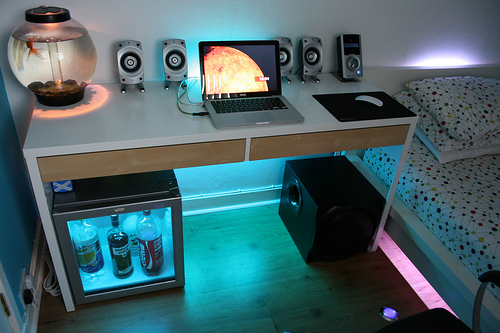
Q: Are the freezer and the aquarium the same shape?
A: No, the aquarium is round and the freezer is square.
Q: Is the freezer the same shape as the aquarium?
A: No, the aquarium is round and the freezer is square.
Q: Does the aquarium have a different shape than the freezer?
A: Yes, the aquarium is round and the freezer is square.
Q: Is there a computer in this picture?
A: Yes, there is a computer.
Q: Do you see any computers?
A: Yes, there is a computer.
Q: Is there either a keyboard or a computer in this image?
A: Yes, there is a computer.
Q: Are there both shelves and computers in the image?
A: No, there is a computer but no shelves.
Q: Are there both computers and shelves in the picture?
A: No, there is a computer but no shelves.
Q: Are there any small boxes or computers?
A: Yes, there is a small computer.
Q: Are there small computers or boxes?
A: Yes, there is a small computer.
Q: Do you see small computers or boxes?
A: Yes, there is a small computer.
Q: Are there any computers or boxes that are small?
A: Yes, the computer is small.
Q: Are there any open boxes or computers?
A: Yes, there is an open computer.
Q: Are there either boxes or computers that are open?
A: Yes, the computer is open.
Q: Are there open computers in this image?
A: Yes, there is an open computer.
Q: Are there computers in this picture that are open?
A: Yes, there is an open computer.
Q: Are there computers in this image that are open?
A: Yes, there is a computer that is open.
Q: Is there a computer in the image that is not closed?
A: Yes, there is a open computer.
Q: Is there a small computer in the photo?
A: Yes, there is a small computer.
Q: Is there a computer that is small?
A: Yes, there is a computer that is small.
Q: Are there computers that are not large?
A: Yes, there is a small computer.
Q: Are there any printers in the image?
A: No, there are no printers.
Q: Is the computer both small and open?
A: Yes, the computer is small and open.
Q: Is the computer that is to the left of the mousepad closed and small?
A: No, the computer is small but open.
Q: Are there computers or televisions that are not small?
A: No, there is a computer but it is small.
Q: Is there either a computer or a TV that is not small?
A: No, there is a computer but it is small.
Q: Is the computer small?
A: Yes, the computer is small.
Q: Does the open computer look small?
A: Yes, the computer is small.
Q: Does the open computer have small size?
A: Yes, the computer is small.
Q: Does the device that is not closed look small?
A: Yes, the computer is small.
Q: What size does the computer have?
A: The computer has small size.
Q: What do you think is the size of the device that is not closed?
A: The computer is small.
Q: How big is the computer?
A: The computer is small.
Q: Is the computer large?
A: No, the computer is small.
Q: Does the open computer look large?
A: No, the computer is small.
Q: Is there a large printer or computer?
A: No, there is a computer but it is small.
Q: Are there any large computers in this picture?
A: No, there is a computer but it is small.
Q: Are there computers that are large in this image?
A: No, there is a computer but it is small.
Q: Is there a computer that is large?
A: No, there is a computer but it is small.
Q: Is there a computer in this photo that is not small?
A: No, there is a computer but it is small.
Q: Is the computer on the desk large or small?
A: The computer is small.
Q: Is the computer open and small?
A: Yes, the computer is open and small.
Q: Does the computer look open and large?
A: No, the computer is open but small.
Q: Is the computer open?
A: Yes, the computer is open.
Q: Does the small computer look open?
A: Yes, the computer is open.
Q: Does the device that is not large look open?
A: Yes, the computer is open.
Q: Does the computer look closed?
A: No, the computer is open.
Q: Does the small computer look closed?
A: No, the computer is open.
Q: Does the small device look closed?
A: No, the computer is open.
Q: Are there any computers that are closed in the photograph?
A: No, there is a computer but it is open.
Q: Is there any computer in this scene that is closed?
A: No, there is a computer but it is open.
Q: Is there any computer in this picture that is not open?
A: No, there is a computer but it is open.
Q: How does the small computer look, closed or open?
A: The computer is open.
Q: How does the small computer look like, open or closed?
A: The computer is open.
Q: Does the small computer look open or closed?
A: The computer is open.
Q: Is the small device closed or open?
A: The computer is open.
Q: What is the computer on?
A: The computer is on the desk.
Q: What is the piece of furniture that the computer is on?
A: The piece of furniture is a desk.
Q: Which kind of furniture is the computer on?
A: The computer is on the desk.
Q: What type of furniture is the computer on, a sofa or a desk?
A: The computer is on a desk.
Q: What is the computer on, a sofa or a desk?
A: The computer is on a desk.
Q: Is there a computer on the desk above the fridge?
A: Yes, there is a computer on the desk.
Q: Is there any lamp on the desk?
A: No, there is a computer on the desk.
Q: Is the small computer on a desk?
A: Yes, the computer is on a desk.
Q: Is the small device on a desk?
A: Yes, the computer is on a desk.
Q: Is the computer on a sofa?
A: No, the computer is on a desk.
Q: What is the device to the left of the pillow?
A: The device is a computer.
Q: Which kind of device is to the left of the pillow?
A: The device is a computer.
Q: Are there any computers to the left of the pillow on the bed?
A: Yes, there is a computer to the left of the pillow.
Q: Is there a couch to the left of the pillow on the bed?
A: No, there is a computer to the left of the pillow.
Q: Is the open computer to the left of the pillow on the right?
A: Yes, the computer is to the left of the pillow.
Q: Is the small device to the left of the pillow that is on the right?
A: Yes, the computer is to the left of the pillow.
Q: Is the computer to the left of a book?
A: No, the computer is to the left of the pillow.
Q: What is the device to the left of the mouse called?
A: The device is a computer.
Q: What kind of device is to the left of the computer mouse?
A: The device is a computer.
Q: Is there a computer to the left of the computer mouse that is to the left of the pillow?
A: Yes, there is a computer to the left of the mouse.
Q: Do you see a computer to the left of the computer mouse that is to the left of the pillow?
A: Yes, there is a computer to the left of the mouse.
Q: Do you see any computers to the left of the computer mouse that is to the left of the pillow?
A: Yes, there is a computer to the left of the mouse.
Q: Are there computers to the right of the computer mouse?
A: No, the computer is to the left of the computer mouse.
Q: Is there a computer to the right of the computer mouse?
A: No, the computer is to the left of the computer mouse.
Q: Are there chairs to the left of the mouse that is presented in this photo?
A: No, there is a computer to the left of the mouse.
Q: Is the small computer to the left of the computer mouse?
A: Yes, the computer is to the left of the computer mouse.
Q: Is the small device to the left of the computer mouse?
A: Yes, the computer is to the left of the computer mouse.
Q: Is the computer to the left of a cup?
A: No, the computer is to the left of the computer mouse.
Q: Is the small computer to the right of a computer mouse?
A: No, the computer is to the left of a computer mouse.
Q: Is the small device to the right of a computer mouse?
A: No, the computer is to the left of a computer mouse.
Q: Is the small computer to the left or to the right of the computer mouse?
A: The computer is to the left of the computer mouse.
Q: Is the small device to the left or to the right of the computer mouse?
A: The computer is to the left of the computer mouse.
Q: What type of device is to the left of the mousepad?
A: The device is a computer.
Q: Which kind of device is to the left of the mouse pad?
A: The device is a computer.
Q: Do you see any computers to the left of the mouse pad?
A: Yes, there is a computer to the left of the mouse pad.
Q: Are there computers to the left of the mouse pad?
A: Yes, there is a computer to the left of the mouse pad.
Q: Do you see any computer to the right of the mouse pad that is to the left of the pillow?
A: No, the computer is to the left of the mousepad.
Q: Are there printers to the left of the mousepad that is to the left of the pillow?
A: No, there is a computer to the left of the mousepad.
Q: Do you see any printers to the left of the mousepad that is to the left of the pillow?
A: No, there is a computer to the left of the mousepad.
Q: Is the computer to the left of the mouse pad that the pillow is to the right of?
A: Yes, the computer is to the left of the mousepad.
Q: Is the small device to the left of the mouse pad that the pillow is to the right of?
A: Yes, the computer is to the left of the mousepad.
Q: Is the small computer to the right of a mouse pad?
A: No, the computer is to the left of a mouse pad.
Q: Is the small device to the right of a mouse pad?
A: No, the computer is to the left of a mouse pad.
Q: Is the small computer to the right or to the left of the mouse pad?
A: The computer is to the left of the mouse pad.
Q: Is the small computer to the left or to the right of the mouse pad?
A: The computer is to the left of the mouse pad.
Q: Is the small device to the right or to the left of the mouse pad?
A: The computer is to the left of the mouse pad.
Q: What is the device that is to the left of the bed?
A: The device is a computer.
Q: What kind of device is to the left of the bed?
A: The device is a computer.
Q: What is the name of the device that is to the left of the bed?
A: The device is a computer.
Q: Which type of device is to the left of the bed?
A: The device is a computer.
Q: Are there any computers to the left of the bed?
A: Yes, there is a computer to the left of the bed.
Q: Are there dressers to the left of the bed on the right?
A: No, there is a computer to the left of the bed.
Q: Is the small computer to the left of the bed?
A: Yes, the computer is to the left of the bed.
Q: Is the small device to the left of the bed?
A: Yes, the computer is to the left of the bed.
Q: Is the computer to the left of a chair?
A: No, the computer is to the left of the bed.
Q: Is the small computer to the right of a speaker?
A: Yes, the computer is to the right of a speaker.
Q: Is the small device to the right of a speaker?
A: Yes, the computer is to the right of a speaker.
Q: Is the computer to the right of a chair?
A: No, the computer is to the right of a speaker.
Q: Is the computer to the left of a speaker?
A: No, the computer is to the right of a speaker.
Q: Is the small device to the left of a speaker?
A: No, the computer is to the right of a speaker.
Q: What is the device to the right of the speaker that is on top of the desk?
A: The device is a computer.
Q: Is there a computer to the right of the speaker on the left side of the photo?
A: Yes, there is a computer to the right of the speaker.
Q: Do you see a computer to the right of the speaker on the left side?
A: Yes, there is a computer to the right of the speaker.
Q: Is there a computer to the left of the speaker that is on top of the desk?
A: No, the computer is to the right of the speaker.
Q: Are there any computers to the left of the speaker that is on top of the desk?
A: No, the computer is to the right of the speaker.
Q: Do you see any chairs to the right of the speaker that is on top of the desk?
A: No, there is a computer to the right of the speaker.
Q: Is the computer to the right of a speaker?
A: Yes, the computer is to the right of a speaker.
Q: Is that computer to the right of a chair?
A: No, the computer is to the right of a speaker.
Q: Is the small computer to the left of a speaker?
A: No, the computer is to the right of a speaker.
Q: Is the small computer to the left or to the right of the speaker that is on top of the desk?
A: The computer is to the right of the speaker.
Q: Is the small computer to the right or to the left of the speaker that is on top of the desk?
A: The computer is to the right of the speaker.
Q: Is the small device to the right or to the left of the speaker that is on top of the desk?
A: The computer is to the right of the speaker.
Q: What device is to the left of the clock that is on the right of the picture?
A: The device is a computer.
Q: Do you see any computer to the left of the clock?
A: Yes, there is a computer to the left of the clock.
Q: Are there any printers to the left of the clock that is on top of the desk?
A: No, there is a computer to the left of the clock.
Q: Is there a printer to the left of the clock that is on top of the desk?
A: No, there is a computer to the left of the clock.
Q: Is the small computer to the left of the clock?
A: Yes, the computer is to the left of the clock.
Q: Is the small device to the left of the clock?
A: Yes, the computer is to the left of the clock.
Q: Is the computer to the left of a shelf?
A: No, the computer is to the left of the speaker.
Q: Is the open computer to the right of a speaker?
A: No, the computer is to the left of a speaker.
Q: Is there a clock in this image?
A: Yes, there is a clock.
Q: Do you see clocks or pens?
A: Yes, there is a clock.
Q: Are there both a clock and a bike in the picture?
A: No, there is a clock but no bikes.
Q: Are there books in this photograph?
A: No, there are no books.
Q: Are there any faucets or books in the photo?
A: No, there are no books or faucets.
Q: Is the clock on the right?
A: Yes, the clock is on the right of the image.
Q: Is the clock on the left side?
A: No, the clock is on the right of the image.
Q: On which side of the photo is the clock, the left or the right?
A: The clock is on the right of the image.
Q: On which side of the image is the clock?
A: The clock is on the right of the image.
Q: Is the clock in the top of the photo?
A: Yes, the clock is in the top of the image.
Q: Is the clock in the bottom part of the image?
A: No, the clock is in the top of the image.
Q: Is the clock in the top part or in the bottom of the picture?
A: The clock is in the top of the image.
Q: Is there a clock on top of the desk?
A: Yes, there is a clock on top of the desk.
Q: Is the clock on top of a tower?
A: No, the clock is on top of the desk.